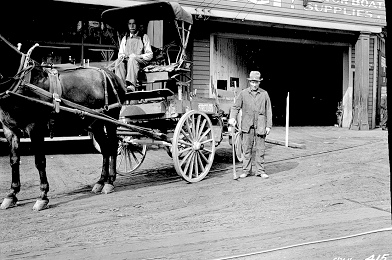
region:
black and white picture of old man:
[227, 46, 290, 198]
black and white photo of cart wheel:
[149, 86, 225, 196]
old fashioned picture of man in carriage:
[85, 9, 218, 174]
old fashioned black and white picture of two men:
[95, 9, 292, 200]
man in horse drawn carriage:
[5, 9, 214, 178]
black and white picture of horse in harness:
[1, 17, 130, 216]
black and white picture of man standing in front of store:
[200, 23, 390, 178]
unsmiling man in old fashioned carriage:
[86, 1, 216, 190]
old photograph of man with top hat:
[216, 48, 298, 205]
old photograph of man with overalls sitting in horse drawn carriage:
[92, 2, 209, 132]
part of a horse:
[1, 40, 127, 208]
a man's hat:
[245, 69, 266, 81]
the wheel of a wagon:
[166, 111, 213, 182]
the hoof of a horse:
[31, 195, 50, 207]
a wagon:
[101, 0, 237, 187]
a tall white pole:
[284, 91, 292, 151]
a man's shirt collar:
[125, 30, 139, 37]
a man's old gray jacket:
[228, 86, 272, 132]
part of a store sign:
[185, 0, 386, 24]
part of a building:
[186, 31, 213, 92]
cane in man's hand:
[218, 116, 246, 177]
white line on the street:
[265, 223, 389, 250]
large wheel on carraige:
[160, 93, 235, 184]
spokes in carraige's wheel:
[178, 126, 213, 161]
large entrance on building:
[198, 25, 376, 147]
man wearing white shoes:
[236, 169, 285, 177]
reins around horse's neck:
[1, 45, 92, 112]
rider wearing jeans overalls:
[99, 27, 172, 56]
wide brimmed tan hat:
[237, 69, 268, 81]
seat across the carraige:
[114, 57, 194, 87]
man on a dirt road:
[226, 60, 283, 186]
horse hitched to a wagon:
[0, 32, 128, 238]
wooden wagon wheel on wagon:
[163, 107, 220, 191]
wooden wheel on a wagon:
[97, 116, 150, 181]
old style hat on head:
[244, 68, 266, 84]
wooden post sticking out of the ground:
[280, 89, 292, 151]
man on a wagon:
[102, 12, 159, 96]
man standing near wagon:
[218, 64, 284, 191]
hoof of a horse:
[24, 193, 51, 213]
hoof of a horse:
[94, 179, 119, 199]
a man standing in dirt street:
[223, 64, 270, 186]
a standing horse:
[2, 35, 122, 213]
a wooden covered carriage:
[89, 6, 253, 178]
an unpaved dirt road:
[9, 143, 383, 252]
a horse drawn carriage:
[4, 5, 208, 208]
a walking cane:
[226, 123, 243, 182]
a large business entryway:
[214, 32, 351, 123]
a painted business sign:
[195, 0, 382, 29]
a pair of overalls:
[107, 25, 147, 86]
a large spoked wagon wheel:
[170, 107, 217, 182]